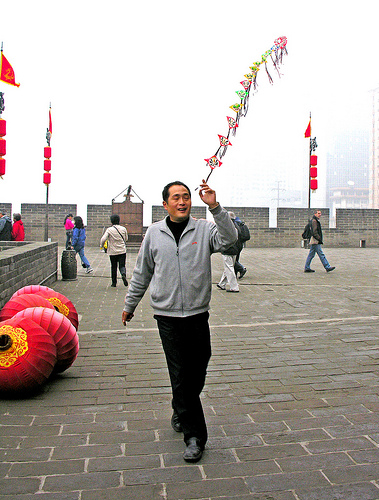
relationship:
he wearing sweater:
[112, 179, 239, 462] [102, 211, 245, 352]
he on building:
[112, 179, 239, 462] [0, 197, 374, 257]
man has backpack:
[291, 192, 347, 266] [288, 211, 317, 245]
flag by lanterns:
[48, 107, 54, 135] [42, 145, 52, 185]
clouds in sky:
[2, 0, 379, 208] [1, 1, 376, 226]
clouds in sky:
[2, 0, 379, 208] [179, 56, 286, 124]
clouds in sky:
[2, 0, 379, 208] [9, 0, 239, 68]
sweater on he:
[123, 202, 239, 319] [112, 179, 239, 462]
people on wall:
[2, 208, 90, 267] [251, 211, 286, 259]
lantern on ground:
[1, 307, 76, 404] [5, 245, 366, 497]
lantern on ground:
[3, 284, 78, 334] [5, 245, 366, 497]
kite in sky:
[197, 35, 288, 194] [0, 13, 347, 199]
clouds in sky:
[2, 0, 379, 208] [304, 47, 334, 88]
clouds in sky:
[2, 0, 315, 151] [1, 1, 376, 226]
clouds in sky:
[2, 0, 379, 208] [3, 6, 370, 193]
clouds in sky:
[2, 0, 379, 208] [83, 19, 186, 154]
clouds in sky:
[2, 0, 379, 208] [107, 43, 159, 136]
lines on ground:
[27, 406, 197, 493] [58, 391, 312, 484]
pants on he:
[151, 314, 214, 439] [112, 179, 239, 462]